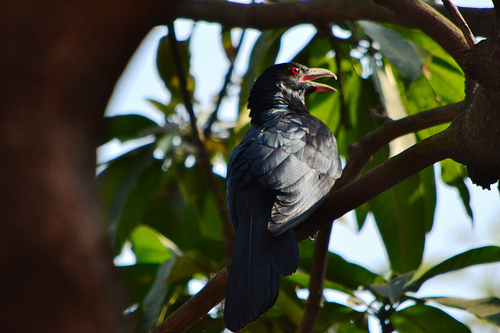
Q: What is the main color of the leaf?
A: Green.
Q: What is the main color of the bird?
A: Black.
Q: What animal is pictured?
A: Bird.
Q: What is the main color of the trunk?
A: Brown.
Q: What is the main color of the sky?
A: White.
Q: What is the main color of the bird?
A: Black.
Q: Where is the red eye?
A: On the bird.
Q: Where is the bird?
A: On a branch.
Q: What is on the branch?
A: A bird.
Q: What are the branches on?
A: A tree.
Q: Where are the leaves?
A: On the branches.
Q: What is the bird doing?
A: Sitting.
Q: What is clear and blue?
A: The sky.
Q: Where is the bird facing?
A: The right.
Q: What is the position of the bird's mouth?
A: Open.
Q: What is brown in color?
A: Branch.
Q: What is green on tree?
A: Leaves.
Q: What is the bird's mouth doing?
A: Opening.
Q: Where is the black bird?
A: In tree.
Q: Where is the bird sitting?
A: In tree.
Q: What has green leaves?
A: Tree.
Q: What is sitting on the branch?
A: Bird.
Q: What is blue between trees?
A: Sky.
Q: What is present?
A: A bird.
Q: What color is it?
A: Grey.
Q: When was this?
A: Daytime.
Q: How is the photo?
A: Clear.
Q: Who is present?
A: Nobody.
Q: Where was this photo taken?
A: A tree.